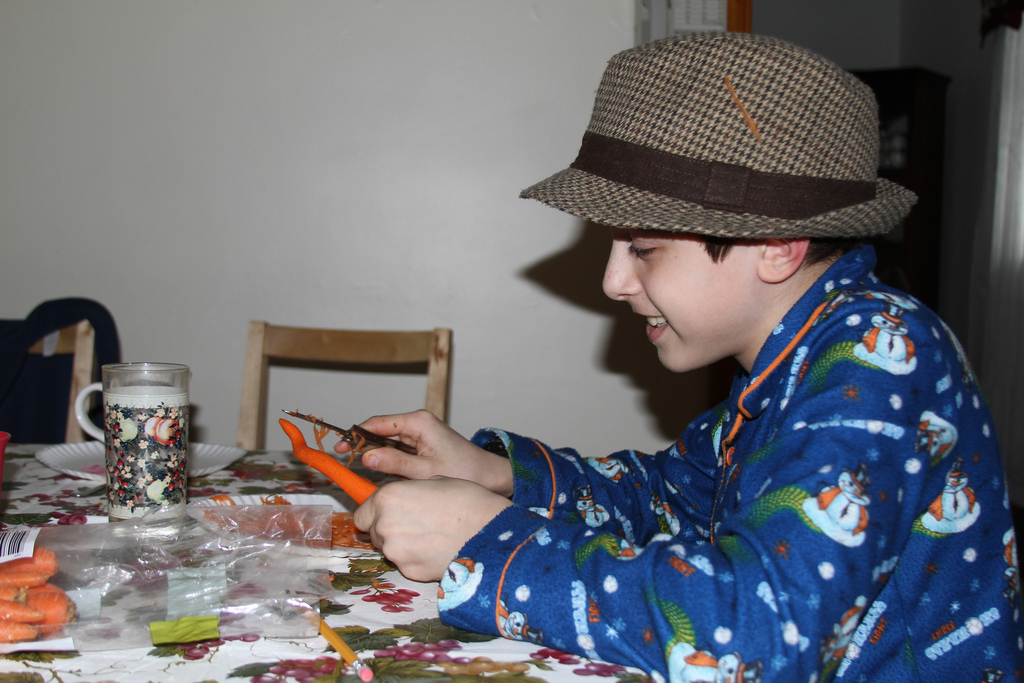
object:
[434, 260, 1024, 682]
pajamas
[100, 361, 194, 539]
glass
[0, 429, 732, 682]
table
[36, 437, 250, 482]
plate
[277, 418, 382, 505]
carrot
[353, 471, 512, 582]
hands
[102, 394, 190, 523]
design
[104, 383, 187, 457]
milk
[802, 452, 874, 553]
snow man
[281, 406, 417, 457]
device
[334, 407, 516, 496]
hand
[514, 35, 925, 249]
hat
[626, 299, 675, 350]
smile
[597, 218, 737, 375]
face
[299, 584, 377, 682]
pencil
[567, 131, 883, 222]
band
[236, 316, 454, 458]
chair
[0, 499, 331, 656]
bag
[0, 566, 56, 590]
carrots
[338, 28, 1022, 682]
boy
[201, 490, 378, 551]
peeling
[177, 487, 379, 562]
plate